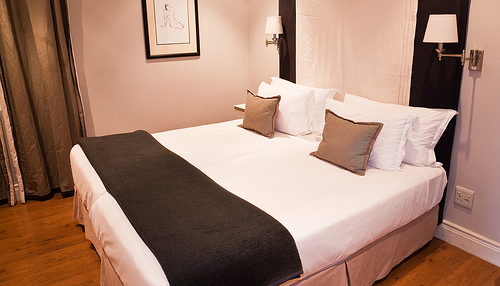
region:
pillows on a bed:
[198, 79, 338, 126]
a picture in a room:
[136, 0, 226, 92]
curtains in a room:
[13, 20, 135, 201]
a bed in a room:
[69, 112, 287, 249]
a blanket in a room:
[74, 88, 240, 243]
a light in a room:
[397, 22, 492, 87]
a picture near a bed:
[96, 21, 226, 160]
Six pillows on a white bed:
[241, 73, 458, 178]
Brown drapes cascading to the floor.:
[0, 0, 97, 204]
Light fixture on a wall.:
[423, 10, 482, 76]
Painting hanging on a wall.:
[141, 0, 198, 63]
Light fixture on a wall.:
[263, 13, 288, 55]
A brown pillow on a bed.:
[308, 109, 378, 177]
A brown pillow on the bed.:
[236, 88, 281, 140]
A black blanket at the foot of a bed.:
[76, 126, 304, 283]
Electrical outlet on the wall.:
[453, 183, 473, 208]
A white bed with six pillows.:
[69, 75, 459, 283]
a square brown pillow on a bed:
[312, 108, 384, 174]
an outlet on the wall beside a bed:
[450, 182, 476, 215]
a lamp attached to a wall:
[421, 12, 489, 74]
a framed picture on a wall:
[139, 0, 203, 58]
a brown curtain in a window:
[0, 0, 93, 207]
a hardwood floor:
[1, 189, 498, 283]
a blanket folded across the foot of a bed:
[74, 127, 309, 284]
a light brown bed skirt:
[68, 187, 442, 284]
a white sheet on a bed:
[69, 115, 447, 284]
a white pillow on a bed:
[316, 99, 420, 170]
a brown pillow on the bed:
[314, 106, 386, 184]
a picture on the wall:
[130, 0, 212, 69]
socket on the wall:
[452, 181, 477, 214]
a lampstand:
[416, 14, 469, 56]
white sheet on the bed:
[274, 157, 327, 208]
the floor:
[4, 226, 74, 271]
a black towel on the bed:
[153, 218, 279, 251]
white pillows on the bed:
[278, 80, 322, 119]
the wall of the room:
[83, 8, 133, 83]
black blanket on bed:
[77, 128, 302, 283]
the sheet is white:
[70, 118, 447, 285]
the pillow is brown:
[311, 109, 381, 177]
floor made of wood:
[0, 190, 495, 284]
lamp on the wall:
[421, 15, 482, 72]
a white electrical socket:
[452, 184, 471, 211]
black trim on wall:
[277, 0, 294, 84]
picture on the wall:
[140, 0, 200, 60]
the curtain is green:
[1, 0, 87, 205]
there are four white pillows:
[256, 73, 455, 174]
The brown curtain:
[3, 7, 119, 207]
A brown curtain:
[2, 7, 98, 199]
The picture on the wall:
[134, 5, 207, 67]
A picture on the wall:
[136, 11, 203, 63]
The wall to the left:
[71, 7, 262, 141]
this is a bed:
[124, 133, 446, 277]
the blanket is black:
[134, 157, 238, 267]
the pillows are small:
[250, 97, 389, 201]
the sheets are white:
[195, 167, 337, 219]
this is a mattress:
[297, 190, 400, 275]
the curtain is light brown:
[4, 45, 101, 202]